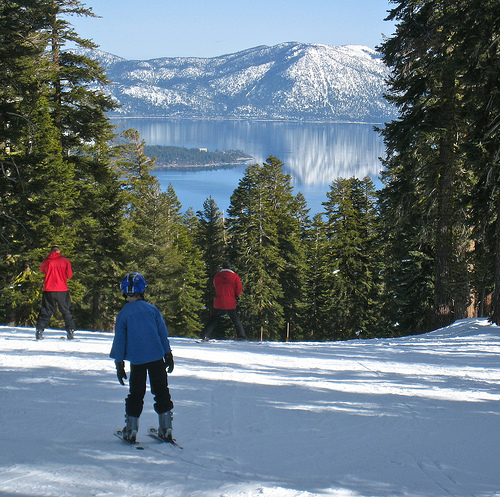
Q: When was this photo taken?
A: Daytime.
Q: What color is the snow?
A: White.